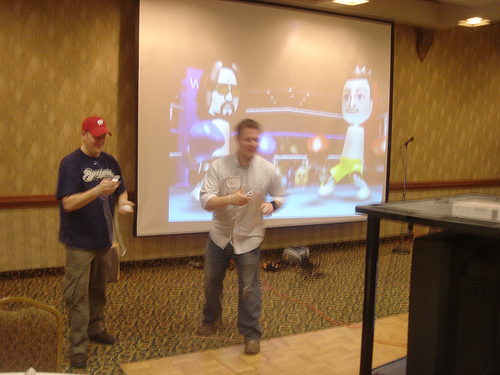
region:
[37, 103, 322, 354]
2 grown men playing Wii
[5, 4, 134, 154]
Dark patterned wallpaper on the walls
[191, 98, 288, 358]
A man in blue jeans and white shirt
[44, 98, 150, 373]
A man in a hat and blue shirt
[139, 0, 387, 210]
Big tv projector screen with a game on it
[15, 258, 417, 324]
Green and brown carpeted floor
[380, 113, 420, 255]
Single black microphone and stand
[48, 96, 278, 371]
Two men playing video games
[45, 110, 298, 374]
Two men wearing brown shoes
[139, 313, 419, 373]
Wooden mat on the floor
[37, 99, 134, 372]
This is a man in a hat.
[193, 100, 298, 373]
This is a man in a white shirt.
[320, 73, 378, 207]
This is a cartoon.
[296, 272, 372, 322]
This is carpet.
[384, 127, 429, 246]
This is a microphone stand.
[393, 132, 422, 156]
This is a microphone.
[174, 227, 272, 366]
These are a man's jeans.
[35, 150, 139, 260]
This is a man's blue tshirt.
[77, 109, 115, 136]
This is a red hat.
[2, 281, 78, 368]
This is a chair.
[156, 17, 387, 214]
The screen behind him is huge.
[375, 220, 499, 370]
The actual TV is shown here.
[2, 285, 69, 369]
A chair is on the left.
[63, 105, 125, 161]
His cap is the color red.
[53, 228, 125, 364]
He is wearing brown cargo pants.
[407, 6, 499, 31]
The light is on the ceiling.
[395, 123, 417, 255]
A microphone is available.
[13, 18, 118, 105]
There is wallpaper on the wall.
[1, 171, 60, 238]
This is called a chair rail.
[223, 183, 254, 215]
The Wii controller is in his hand.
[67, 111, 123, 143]
Red Cap On guy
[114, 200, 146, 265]
Wii Remote in hand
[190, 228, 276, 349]
Blue Jeans on man's body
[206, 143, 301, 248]
White button up shirt on man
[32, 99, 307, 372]
Two guys Playing Wii game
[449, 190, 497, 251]
Wii Box game on top of stand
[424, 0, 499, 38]
Basement Lights in Ceiling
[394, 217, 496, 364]
Television set on stand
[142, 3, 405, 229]
Projection screen on the wall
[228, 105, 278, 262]
Man with a smile on his face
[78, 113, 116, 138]
a red baseball cap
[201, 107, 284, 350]
a man holding a wii remote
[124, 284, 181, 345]
pattern on carpet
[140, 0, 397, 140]
a projection screen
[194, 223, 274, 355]
a person in blue jeans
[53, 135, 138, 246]
a man in a blue shirt with white writing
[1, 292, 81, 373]
gold colored frame of a chair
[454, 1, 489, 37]
light in the ceiling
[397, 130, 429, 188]
microphone on a stand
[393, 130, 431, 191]
microphone next to the wall